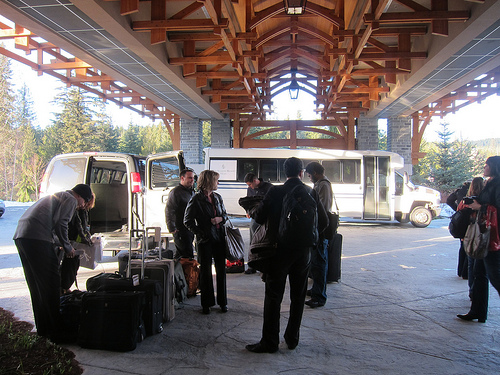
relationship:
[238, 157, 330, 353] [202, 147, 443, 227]
group of people waiting for ride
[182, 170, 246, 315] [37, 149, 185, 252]
person waiting for ride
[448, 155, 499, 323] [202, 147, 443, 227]
person waiting for ride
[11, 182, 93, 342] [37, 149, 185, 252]
person waiting for ride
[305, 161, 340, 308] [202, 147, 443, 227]
person waiting for ride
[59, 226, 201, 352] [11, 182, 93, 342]
luggages of person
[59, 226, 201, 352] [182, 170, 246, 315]
luggages of person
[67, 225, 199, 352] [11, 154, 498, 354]
luggages of people waiting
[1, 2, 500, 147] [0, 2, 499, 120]
structure has an overhead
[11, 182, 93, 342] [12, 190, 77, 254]
man wearing a shirt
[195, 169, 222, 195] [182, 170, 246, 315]
turned head of a woman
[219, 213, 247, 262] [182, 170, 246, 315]
purse of a woman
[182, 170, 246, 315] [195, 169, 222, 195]
woman with head turned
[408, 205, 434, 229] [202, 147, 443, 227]
front tire of a shuttle bus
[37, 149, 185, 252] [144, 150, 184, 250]
van with door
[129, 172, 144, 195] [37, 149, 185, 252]
tail-light of a van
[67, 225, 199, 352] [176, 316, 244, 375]
row of luggage sitting on ground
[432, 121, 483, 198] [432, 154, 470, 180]
bush with leaves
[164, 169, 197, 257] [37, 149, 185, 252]
person standing beside a vehicle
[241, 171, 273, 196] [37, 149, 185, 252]
person standing beside a vehicle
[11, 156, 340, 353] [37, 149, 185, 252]
group of people standing beside a vehicle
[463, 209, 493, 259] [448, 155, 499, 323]
bag on side of a person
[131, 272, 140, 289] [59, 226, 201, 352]
tag on top of luggages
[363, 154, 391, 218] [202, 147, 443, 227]
large doors on side of shuttle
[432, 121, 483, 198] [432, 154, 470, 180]
tree with green leaves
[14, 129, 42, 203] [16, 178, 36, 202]
tree with green leaves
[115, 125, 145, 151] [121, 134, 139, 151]
tree with green leaves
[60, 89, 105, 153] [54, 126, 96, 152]
tree with green leaves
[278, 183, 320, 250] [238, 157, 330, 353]
backpack on back of a group of people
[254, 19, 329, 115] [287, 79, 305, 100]
ceiling has a light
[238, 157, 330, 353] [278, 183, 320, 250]
group of people wearing a backpack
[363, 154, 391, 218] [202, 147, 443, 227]
large doors on bus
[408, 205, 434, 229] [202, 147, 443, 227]
front tire on bus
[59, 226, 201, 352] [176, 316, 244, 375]
luggages on ground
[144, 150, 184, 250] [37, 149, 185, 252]
open back door of van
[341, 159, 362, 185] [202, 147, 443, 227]
window on bus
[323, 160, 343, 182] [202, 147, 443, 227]
window on bus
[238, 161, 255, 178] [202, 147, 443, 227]
window on bus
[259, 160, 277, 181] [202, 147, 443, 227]
window on bus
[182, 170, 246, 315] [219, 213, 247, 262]
woman carrying a bag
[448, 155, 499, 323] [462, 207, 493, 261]
woman carrying a bag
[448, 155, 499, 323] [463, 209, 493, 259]
woman carrying bag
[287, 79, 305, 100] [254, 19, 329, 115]
light in ceiling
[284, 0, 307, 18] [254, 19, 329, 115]
light in ceiling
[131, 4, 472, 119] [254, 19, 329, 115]
beams exposed on ceiling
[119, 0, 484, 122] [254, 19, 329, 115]
beams exposed on ceiling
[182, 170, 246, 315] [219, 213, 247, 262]
woman holding bag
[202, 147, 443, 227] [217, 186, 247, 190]
bus has blue stripe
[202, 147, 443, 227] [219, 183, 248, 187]
bus has blue stripe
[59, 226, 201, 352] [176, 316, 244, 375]
luggages sitting on ground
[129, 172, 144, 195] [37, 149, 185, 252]
tail-light of van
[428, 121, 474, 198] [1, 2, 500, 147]
pine tree in front of building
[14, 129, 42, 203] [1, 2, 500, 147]
pine tree in front of building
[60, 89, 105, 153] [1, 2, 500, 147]
pine tree in front of building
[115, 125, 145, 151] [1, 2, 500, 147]
pine tree in front of building